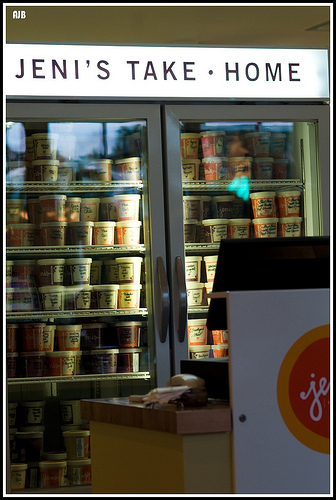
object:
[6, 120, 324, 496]
behind glass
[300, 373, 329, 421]
letters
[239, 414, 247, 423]
screw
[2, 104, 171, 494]
doors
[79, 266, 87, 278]
lettering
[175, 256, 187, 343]
door handle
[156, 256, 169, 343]
door handle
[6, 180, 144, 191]
rack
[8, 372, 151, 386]
shelving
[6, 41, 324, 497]
unit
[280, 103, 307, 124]
ground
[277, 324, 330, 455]
logo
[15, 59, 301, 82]
letter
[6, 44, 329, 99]
sign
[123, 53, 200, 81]
green trees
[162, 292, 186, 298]
reflection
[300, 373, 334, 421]
writing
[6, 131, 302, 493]
case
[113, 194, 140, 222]
ice cream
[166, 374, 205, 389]
telephone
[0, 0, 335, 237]
background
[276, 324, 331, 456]
circle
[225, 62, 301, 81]
word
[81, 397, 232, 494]
counter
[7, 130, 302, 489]
container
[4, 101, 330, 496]
fridge